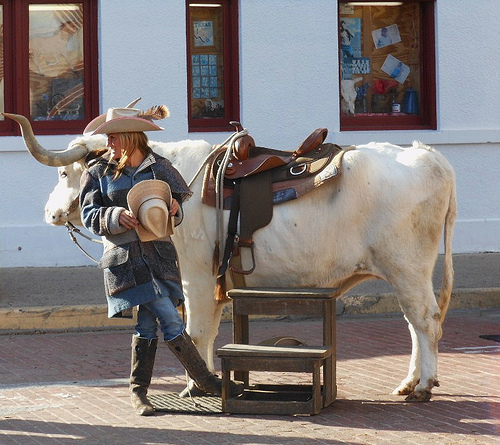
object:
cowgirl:
[79, 106, 246, 415]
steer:
[1, 97, 457, 415]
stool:
[213, 284, 341, 416]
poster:
[193, 20, 215, 47]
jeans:
[134, 293, 186, 342]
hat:
[83, 106, 166, 137]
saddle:
[210, 120, 341, 275]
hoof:
[403, 388, 431, 404]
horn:
[1, 112, 89, 167]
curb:
[0, 286, 498, 335]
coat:
[79, 151, 193, 319]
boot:
[163, 328, 246, 397]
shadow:
[155, 393, 499, 435]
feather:
[132, 104, 170, 121]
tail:
[436, 184, 457, 340]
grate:
[146, 392, 223, 414]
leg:
[391, 253, 441, 389]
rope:
[187, 127, 250, 301]